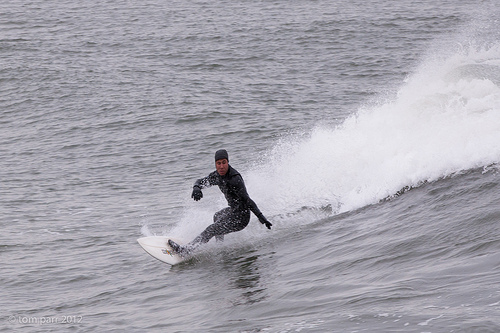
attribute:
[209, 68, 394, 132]
waves — gray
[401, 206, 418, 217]
sky — Blue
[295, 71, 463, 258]
waves — gray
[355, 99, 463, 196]
waves ocean — gray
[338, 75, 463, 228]
waves — white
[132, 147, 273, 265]
surfer — male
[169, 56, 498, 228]
wave — gray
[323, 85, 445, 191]
waves — white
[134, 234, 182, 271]
board — White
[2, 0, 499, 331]
ocean — white, gray, grey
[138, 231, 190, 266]
board — White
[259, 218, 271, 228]
arm — Extended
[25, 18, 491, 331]
ocean — Blue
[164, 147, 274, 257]
surfer — Surfing, male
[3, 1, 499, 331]
wave — white, gray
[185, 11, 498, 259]
wave — gray, white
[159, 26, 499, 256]
wave — white, gray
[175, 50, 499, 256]
wave — gray, white